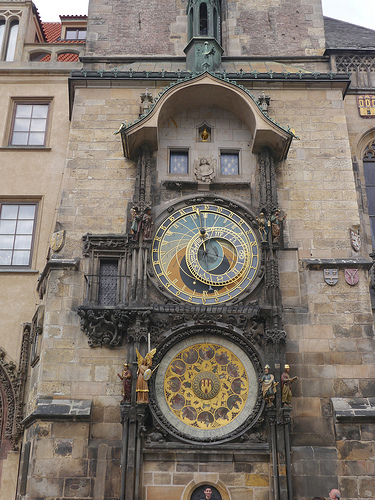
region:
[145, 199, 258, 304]
fancy clock face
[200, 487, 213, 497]
person standing under arch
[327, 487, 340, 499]
person looking at building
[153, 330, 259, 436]
rose style glass window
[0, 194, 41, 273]
rectangular window on the building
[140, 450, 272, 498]
brick material on the building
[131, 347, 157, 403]
statue of an angel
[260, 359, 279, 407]
statue of a man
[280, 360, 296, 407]
statue of a man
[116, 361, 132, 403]
statue of a man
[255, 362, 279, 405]
Statue next to round ornate clock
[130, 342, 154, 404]
Angel statue next to round ornate clock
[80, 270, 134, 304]
Small balcony on building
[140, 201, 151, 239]
Statue next to round ornate clock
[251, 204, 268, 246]
Statue next to round ornate clock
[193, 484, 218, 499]
Man in front of building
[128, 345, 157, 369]
Large golden wings on angel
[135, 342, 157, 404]
Angel holding round shield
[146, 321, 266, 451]
Large round clock above man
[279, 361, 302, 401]
Small statue holding book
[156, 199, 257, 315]
The medieval clock is circular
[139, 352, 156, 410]
An angel sculpture is gold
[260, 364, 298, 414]
Two sculptures on a column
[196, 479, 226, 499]
A person in an archway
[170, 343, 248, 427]
A circle with gold artwork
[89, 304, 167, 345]
A decorative stone ledge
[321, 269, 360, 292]
Two shields mounted on the wall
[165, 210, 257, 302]
A circle within a circle within a circle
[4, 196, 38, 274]
A single window stands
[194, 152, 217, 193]
A stone sculpture between windows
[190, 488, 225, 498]
Man standing in front of clock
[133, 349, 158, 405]
Golden statue of an angel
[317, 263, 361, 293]
carvings of sheilds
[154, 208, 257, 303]
gold and black clock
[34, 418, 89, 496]
worn out brick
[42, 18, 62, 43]
brown roof tile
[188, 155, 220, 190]
statue of angel on top of clock face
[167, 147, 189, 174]
star pattern in window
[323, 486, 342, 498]
bald man looking at building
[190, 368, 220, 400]
castle in the middle of clock face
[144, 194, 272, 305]
a round clock on a building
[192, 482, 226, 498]
a mans head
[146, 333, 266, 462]
pictures in a circle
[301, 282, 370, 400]
stone wall on a building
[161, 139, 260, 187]
small windows on building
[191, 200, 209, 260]
hands on a clock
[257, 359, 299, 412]
small statues on wall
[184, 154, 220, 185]
small statue above clock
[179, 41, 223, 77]
a weather vane on point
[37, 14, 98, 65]
a red slate roof